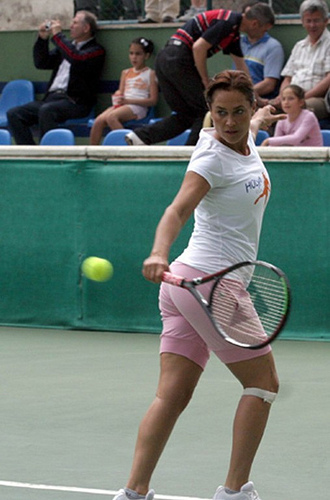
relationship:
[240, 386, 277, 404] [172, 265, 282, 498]
band around leg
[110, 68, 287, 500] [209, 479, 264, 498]
woman wearing white shoe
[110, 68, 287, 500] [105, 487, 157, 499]
woman wearing white shoe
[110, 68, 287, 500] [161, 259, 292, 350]
woman holding racket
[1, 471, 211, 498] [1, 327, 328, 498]
white line on court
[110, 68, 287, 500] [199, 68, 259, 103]
woman has hair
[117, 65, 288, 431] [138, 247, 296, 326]
woman holding racket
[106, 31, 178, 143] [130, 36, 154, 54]
girl has hair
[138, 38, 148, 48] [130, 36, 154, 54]
hair bow in hair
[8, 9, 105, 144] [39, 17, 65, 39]
man holding camera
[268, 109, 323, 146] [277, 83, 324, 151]
pink shirt on gril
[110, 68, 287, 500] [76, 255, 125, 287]
woman hitting tennis ball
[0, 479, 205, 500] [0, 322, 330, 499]
white line on court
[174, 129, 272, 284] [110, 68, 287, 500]
t-shirt on woman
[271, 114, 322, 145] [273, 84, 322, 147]
pink shirt on girl